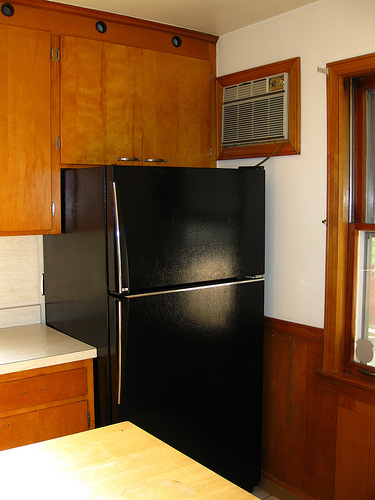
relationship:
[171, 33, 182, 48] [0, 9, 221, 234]
black light on cabinet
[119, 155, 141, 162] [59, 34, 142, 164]
chrome handle on cabinet door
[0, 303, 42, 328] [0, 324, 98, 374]
backsplash on counter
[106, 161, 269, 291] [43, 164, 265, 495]
freezer door on fridge